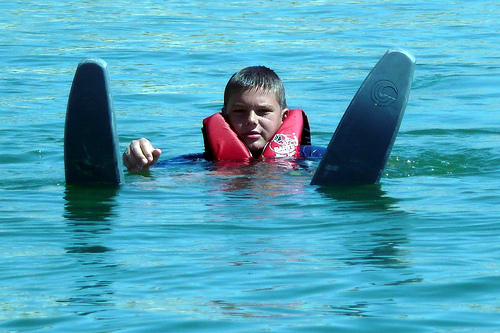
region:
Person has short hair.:
[217, 53, 278, 94]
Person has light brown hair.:
[226, 52, 291, 95]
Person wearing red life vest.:
[208, 119, 323, 189]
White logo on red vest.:
[276, 123, 317, 180]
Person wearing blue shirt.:
[163, 142, 205, 174]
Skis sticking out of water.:
[308, 88, 404, 215]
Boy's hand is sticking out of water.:
[123, 120, 165, 183]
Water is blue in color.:
[193, 230, 352, 311]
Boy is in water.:
[157, 83, 340, 248]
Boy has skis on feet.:
[53, 100, 365, 250]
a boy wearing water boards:
[53, 25, 420, 224]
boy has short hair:
[189, 56, 325, 190]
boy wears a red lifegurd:
[176, 54, 334, 181]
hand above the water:
[114, 117, 173, 187]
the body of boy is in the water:
[119, 53, 344, 215]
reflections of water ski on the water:
[310, 185, 435, 300]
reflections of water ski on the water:
[50, 185, 130, 315]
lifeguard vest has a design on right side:
[191, 96, 319, 176]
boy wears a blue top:
[136, 59, 330, 195]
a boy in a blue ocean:
[8, 6, 485, 331]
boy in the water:
[50, 27, 436, 221]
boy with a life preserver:
[187, 64, 320, 175]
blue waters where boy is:
[22, 222, 467, 308]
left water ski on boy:
[315, 30, 428, 210]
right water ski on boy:
[57, 48, 129, 205]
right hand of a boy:
[119, 130, 167, 185]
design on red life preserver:
[269, 133, 305, 166]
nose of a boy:
[242, 115, 261, 127]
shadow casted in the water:
[59, 184, 130, 225]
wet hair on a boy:
[229, 62, 291, 92]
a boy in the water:
[48, 10, 430, 240]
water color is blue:
[5, 5, 497, 331]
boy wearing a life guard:
[165, 54, 327, 213]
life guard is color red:
[201, 110, 313, 171]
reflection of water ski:
[325, 189, 427, 307]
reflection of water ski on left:
[47, 204, 138, 318]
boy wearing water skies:
[41, 19, 430, 236]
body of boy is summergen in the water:
[117, 46, 341, 202]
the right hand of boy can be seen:
[116, 54, 342, 196]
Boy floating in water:
[58, 35, 419, 193]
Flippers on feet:
[54, 50, 430, 201]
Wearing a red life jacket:
[199, 105, 314, 170]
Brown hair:
[218, 58, 297, 112]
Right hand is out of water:
[119, 133, 175, 181]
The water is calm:
[12, 15, 483, 320]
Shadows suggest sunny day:
[60, 99, 395, 224]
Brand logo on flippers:
[369, 77, 402, 119]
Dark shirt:
[301, 142, 333, 164]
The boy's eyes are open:
[223, 95, 282, 135]